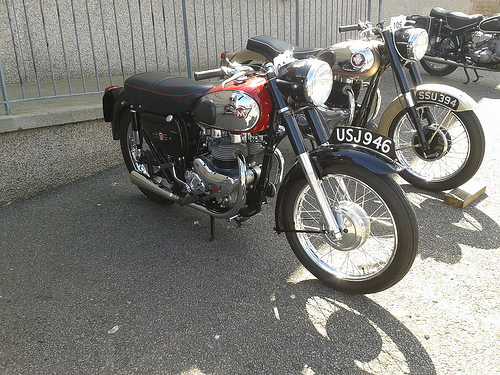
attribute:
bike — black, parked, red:
[100, 46, 419, 295]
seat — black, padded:
[122, 71, 215, 113]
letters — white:
[336, 128, 363, 143]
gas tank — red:
[191, 75, 275, 134]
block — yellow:
[443, 179, 487, 210]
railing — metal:
[0, 0, 372, 117]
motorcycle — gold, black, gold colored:
[218, 13, 486, 192]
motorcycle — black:
[404, 7, 500, 85]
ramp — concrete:
[0, 70, 222, 209]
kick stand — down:
[207, 216, 217, 243]